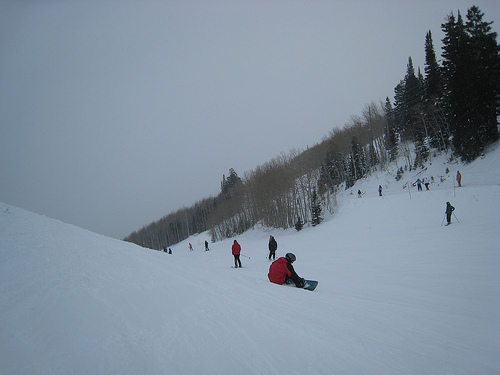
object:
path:
[344, 165, 484, 199]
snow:
[0, 129, 499, 373]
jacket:
[420, 178, 428, 186]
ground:
[150, 109, 498, 374]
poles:
[450, 210, 459, 226]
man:
[266, 250, 309, 288]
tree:
[216, 165, 248, 210]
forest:
[120, 5, 499, 252]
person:
[228, 238, 242, 270]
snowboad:
[292, 279, 318, 292]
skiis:
[231, 264, 245, 267]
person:
[442, 202, 455, 227]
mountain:
[0, 201, 499, 373]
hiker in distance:
[376, 183, 383, 199]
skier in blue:
[203, 238, 211, 251]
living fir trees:
[304, 3, 499, 226]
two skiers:
[412, 175, 430, 193]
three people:
[413, 170, 466, 193]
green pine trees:
[382, 95, 401, 163]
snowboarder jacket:
[266, 256, 296, 286]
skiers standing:
[265, 236, 279, 263]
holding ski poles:
[435, 200, 459, 228]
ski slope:
[0, 199, 499, 374]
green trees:
[342, 134, 364, 188]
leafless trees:
[122, 97, 459, 252]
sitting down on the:
[266, 253, 320, 290]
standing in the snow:
[443, 200, 456, 227]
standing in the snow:
[375, 184, 383, 197]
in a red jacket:
[231, 242, 242, 257]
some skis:
[443, 220, 453, 228]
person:
[354, 187, 362, 199]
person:
[376, 183, 384, 198]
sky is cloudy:
[0, 0, 499, 242]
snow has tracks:
[143, 255, 278, 374]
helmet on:
[283, 253, 296, 264]